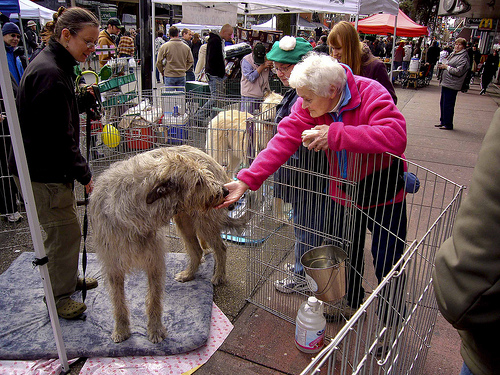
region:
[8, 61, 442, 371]
canine enclosed in pen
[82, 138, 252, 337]
canine in the enclosure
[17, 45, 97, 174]
jacket on the person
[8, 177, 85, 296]
pants on the person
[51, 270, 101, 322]
shoes on the person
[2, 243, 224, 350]
pad canine and human stand on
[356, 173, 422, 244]
metal network of enclosure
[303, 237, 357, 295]
metal pail in enclosure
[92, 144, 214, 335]
this is a dog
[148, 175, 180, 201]
this is the ear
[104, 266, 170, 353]
these are the legs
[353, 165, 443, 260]
this is the cage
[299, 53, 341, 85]
this is the hair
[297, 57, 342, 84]
the hair is white in color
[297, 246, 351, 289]
this is a bucket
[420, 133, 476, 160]
this is the floor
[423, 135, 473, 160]
the floor is made of stone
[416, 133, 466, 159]
the stone is grey in color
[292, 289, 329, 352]
this is a bottle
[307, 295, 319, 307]
the lid is white in color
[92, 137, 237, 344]
this is a dog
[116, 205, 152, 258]
the fur is white in color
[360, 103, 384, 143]
the jacket is pink in color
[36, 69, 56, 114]
the jacket is black in color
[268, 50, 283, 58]
the hat is green in color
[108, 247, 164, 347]
these are the legs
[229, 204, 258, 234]
this is the tail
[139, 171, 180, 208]
this is an ear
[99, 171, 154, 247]
the dog is fury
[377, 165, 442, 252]
this is a cage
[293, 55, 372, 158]
this is an old man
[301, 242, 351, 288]
this is a bucket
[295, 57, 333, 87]
the hair is white in color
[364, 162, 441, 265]
the cage is metallic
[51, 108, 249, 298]
animal in the cage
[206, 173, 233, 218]
nose of the animal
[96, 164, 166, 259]
fur on the animal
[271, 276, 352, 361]
bottle on the ground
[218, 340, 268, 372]
line on the ground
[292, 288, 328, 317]
cap on the bottle